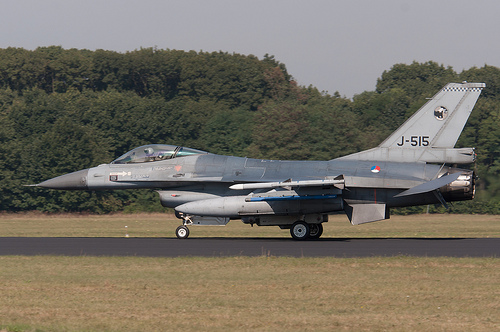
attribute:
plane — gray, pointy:
[18, 71, 498, 243]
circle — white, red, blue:
[362, 164, 396, 187]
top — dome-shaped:
[106, 140, 213, 167]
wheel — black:
[288, 220, 308, 239]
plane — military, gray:
[74, 65, 466, 237]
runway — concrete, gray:
[3, 230, 491, 265]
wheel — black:
[176, 223, 189, 238]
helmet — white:
[141, 146, 155, 156]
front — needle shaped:
[17, 177, 36, 190]